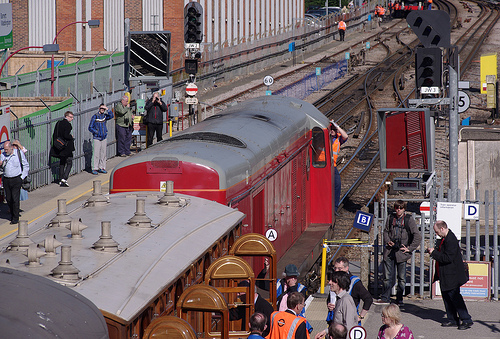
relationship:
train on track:
[72, 70, 354, 330] [349, 51, 396, 108]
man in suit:
[86, 91, 120, 183] [51, 114, 78, 153]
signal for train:
[429, 81, 470, 138] [72, 70, 354, 330]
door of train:
[295, 110, 354, 231] [72, 70, 354, 330]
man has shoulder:
[86, 91, 120, 183] [85, 104, 106, 125]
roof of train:
[109, 95, 330, 192] [72, 70, 354, 330]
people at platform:
[11, 61, 200, 233] [6, 90, 248, 274]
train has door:
[72, 70, 354, 330] [295, 110, 354, 231]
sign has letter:
[442, 85, 486, 118] [441, 93, 472, 116]